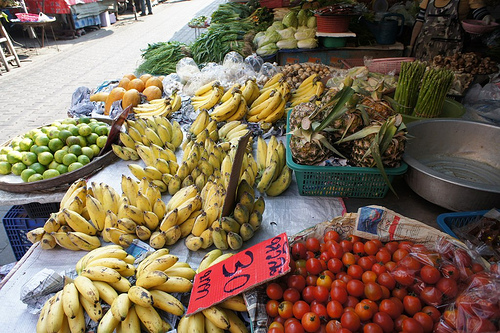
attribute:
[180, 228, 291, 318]
sign — red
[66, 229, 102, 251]
bananas — on display, bunched, for sale, yellow, sweet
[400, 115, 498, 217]
pan — large, empty, metal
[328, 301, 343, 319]
tomatoes — wrapped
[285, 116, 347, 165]
pineapples — on display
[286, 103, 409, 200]
display — plastic, green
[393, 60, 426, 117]
asparagus — for sale, on display, straight up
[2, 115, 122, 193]
tray — round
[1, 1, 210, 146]
street — stone, narrow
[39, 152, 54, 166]
limes — piled